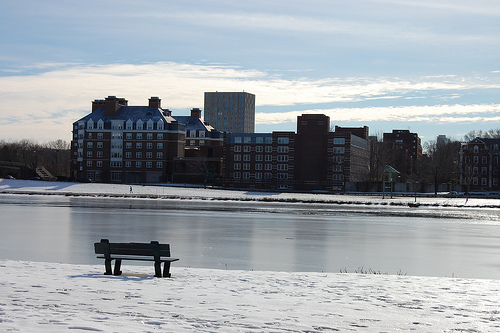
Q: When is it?
A: Day time.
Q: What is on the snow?
A: Bench.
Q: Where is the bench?
A: On the snow.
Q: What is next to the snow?
A: Water.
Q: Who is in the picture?
A: No one.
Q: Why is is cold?
A: Winter.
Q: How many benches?
A: 1.